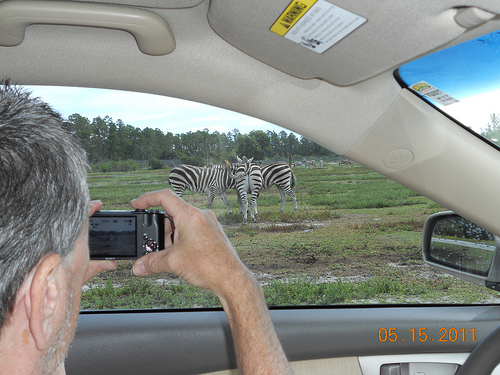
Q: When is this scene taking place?
A: Daytime.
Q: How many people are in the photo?
A: One.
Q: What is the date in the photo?
A: May 15th, 2011.